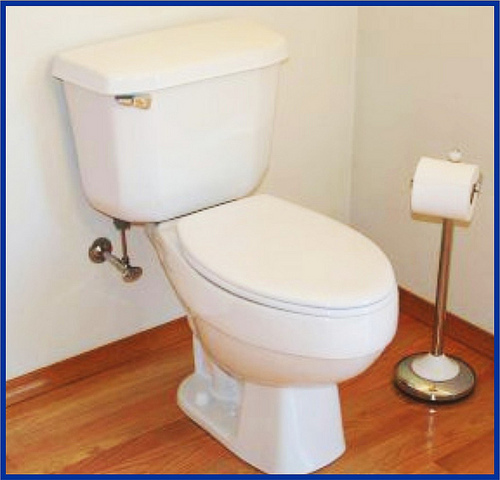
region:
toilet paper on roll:
[409, 153, 475, 223]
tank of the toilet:
[56, 0, 288, 81]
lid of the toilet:
[197, 193, 392, 300]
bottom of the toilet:
[122, 373, 326, 465]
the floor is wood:
[65, 378, 157, 465]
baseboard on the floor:
[38, 350, 120, 387]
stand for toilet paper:
[387, 200, 487, 411]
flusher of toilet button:
[105, 78, 155, 113]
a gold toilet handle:
[112, 91, 154, 112]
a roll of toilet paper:
[409, 149, 481, 226]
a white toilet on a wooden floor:
[48, 16, 398, 473]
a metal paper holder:
[393, 146, 481, 408]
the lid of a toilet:
[170, 188, 401, 308]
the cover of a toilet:
[174, 194, 394, 310]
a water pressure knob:
[118, 262, 148, 284]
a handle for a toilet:
[110, 92, 155, 111]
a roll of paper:
[400, 155, 485, 229]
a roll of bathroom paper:
[411, 153, 483, 223]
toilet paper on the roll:
[373, 158, 463, 410]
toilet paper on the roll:
[389, 179, 467, 413]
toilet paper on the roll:
[411, 142, 471, 408]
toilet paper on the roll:
[413, 180, 480, 428]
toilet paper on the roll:
[379, 160, 472, 397]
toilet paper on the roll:
[398, 146, 468, 408]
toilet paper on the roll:
[394, 154, 462, 404]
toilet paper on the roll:
[393, 153, 468, 410]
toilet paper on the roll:
[368, 144, 472, 398]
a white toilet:
[50, 18, 400, 473]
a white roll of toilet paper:
[411, 159, 480, 225]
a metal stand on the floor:
[393, 218, 475, 398]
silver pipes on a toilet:
[89, 220, 142, 280]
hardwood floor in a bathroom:
[7, 311, 492, 471]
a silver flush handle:
[113, 95, 148, 111]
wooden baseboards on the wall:
[7, 289, 493, 407]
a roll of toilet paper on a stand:
[393, 151, 480, 403]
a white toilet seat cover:
[178, 191, 395, 312]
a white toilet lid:
[51, 16, 288, 96]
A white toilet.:
[43, 23, 404, 473]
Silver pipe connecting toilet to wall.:
[80, 218, 147, 280]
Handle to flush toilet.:
[112, 85, 163, 115]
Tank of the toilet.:
[58, 9, 300, 223]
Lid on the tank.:
[58, 20, 295, 88]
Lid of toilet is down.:
[167, 201, 397, 318]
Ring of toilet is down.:
[168, 192, 398, 323]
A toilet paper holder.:
[400, 139, 490, 401]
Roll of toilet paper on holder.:
[405, 151, 484, 226]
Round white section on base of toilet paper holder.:
[406, 343, 466, 382]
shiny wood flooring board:
[396, 400, 495, 470]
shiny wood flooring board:
[27, 388, 172, 458]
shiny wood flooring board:
[17, 410, 190, 466]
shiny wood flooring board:
[101, 433, 213, 471]